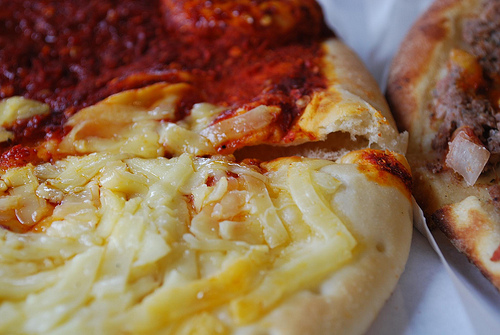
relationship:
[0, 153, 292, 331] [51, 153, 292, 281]
cheesy very cheesy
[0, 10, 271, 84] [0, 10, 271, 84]
sauce red sauce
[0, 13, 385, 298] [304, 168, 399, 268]
pizza crust good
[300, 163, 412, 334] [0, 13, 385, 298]
crust sheet pizza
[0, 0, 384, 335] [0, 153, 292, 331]
pizza pizzas cheesy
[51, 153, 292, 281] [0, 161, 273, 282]
cheese and onions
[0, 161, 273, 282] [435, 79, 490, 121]
onions and meat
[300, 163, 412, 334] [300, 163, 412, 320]
crust pizza crust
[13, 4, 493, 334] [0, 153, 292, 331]
scene of cheesy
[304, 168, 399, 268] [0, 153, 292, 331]
good looking cheesy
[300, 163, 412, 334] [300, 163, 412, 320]
crust toasted crust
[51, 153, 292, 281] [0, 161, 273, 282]
melt yellow cheese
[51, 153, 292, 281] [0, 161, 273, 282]
slice of onions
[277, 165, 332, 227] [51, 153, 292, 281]
close up cheese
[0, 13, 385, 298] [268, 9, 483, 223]
pizza next another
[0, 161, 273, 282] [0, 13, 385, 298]
onions on pizza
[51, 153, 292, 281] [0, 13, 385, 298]
cheese on pizza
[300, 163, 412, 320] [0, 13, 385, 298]
edge of pizza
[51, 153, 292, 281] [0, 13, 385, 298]
yellow part pizza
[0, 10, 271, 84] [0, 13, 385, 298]
red section pizza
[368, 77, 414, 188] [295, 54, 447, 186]
edge of pizzas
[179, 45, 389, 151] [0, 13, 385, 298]
part of pizza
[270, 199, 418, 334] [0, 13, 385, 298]
outer part pizza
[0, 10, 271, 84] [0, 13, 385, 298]
sauce part pizza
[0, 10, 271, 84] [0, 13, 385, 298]
sauce on pizza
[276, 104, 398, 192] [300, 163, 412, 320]
doughy pizza crust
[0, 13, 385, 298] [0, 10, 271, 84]
pizza with sauce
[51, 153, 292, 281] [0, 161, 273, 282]
pieces of onions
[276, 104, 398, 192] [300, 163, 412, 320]
small pizza crust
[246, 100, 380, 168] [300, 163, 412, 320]
air pockets crust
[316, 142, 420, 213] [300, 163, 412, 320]
crispy edges crust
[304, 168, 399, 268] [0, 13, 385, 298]
color white pizza